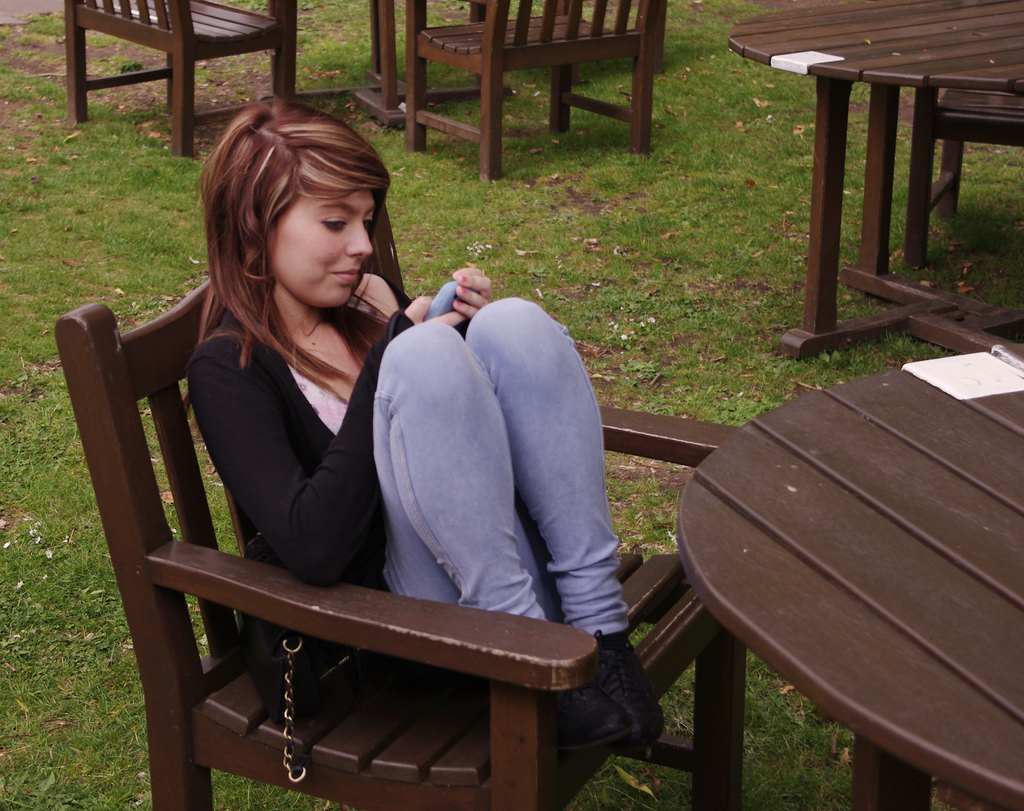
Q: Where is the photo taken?
A: In a park.